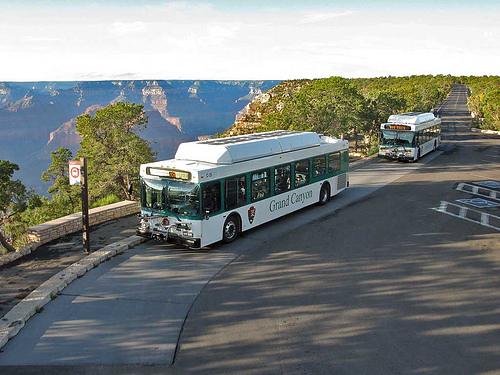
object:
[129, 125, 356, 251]
bus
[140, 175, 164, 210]
windshield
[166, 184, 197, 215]
windshield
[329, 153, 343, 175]
window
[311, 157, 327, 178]
window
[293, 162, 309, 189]
window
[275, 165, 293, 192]
window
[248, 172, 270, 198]
window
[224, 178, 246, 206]
window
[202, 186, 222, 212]
window